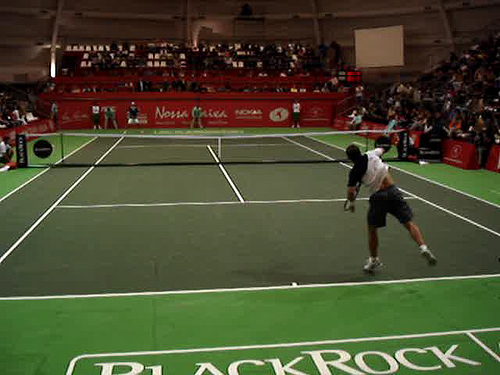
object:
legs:
[361, 196, 388, 273]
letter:
[424, 343, 483, 368]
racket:
[397, 118, 411, 128]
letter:
[93, 357, 144, 373]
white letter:
[227, 359, 265, 374]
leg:
[385, 191, 440, 267]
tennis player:
[344, 143, 440, 271]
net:
[26, 132, 400, 165]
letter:
[299, 349, 365, 375]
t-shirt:
[347, 148, 389, 193]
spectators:
[51, 42, 364, 94]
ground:
[1, 126, 499, 373]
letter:
[93, 361, 146, 372]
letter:
[147, 364, 165, 374]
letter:
[191, 361, 223, 374]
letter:
[263, 354, 309, 375]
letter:
[353, 349, 399, 374]